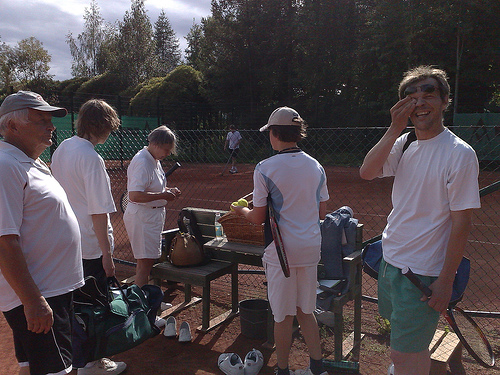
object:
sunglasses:
[404, 83, 439, 95]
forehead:
[404, 79, 438, 94]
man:
[358, 64, 483, 375]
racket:
[399, 266, 496, 369]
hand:
[421, 277, 453, 313]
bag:
[65, 274, 167, 359]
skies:
[1, 1, 211, 65]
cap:
[2, 90, 68, 119]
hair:
[1, 108, 30, 131]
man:
[0, 88, 88, 374]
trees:
[1, 30, 55, 85]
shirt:
[382, 127, 482, 275]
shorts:
[374, 254, 448, 350]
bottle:
[212, 211, 224, 241]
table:
[203, 225, 365, 276]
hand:
[388, 95, 416, 128]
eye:
[405, 95, 417, 102]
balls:
[237, 198, 250, 208]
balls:
[229, 201, 239, 210]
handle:
[400, 266, 448, 311]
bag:
[166, 229, 208, 267]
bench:
[413, 325, 462, 375]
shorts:
[3, 287, 72, 374]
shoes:
[216, 353, 244, 375]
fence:
[1, 122, 500, 339]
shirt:
[252, 150, 330, 266]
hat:
[257, 106, 304, 133]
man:
[232, 105, 333, 375]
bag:
[360, 233, 471, 311]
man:
[50, 97, 126, 374]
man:
[223, 125, 242, 174]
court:
[9, 152, 500, 336]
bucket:
[238, 296, 272, 341]